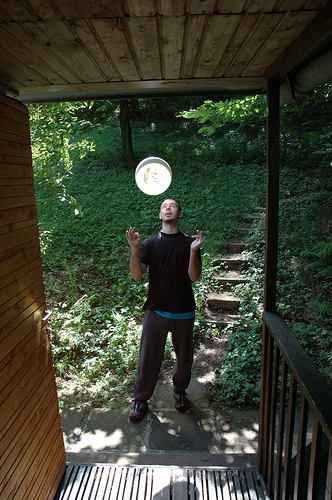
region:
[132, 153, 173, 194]
A white ball in the air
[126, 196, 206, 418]
A man outside catching the ball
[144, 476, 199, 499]
The shadow of the ball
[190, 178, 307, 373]
A pathway with steps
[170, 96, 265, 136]
A branch with leaves on it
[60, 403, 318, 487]
concrete slab patio outside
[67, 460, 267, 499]
The porch of the house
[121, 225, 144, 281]
The man's right arm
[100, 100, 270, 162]
A wooded area outside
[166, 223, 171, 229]
The man's Adams apple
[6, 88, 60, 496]
Light pine wood siding on house.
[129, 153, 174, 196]
White freebie in the air.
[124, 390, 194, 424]
Black, gray and red tennis shoes.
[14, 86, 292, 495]
Covered porch made of wood.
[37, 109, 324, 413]
Lots of green foliage for landscape.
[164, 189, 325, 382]
Wooden slates in dirt for natural stairs.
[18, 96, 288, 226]
Very little sun coming through the trees.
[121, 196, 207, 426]
Navy blue tee shirt with light blue shirt underneath.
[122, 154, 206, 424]
Man trying to catch freebie as it comes down.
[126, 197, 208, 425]
Comfortable sweatpants for kicking back.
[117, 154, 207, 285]
a man is standing under a pie pan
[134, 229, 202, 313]
the man is wearing a dark blue t-shirt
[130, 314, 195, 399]
the man's pants are warm ups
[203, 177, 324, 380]
a stepped pathway winds up a hill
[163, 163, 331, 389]
the pathway is surrounded by ivy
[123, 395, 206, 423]
the boy has tennis shoes on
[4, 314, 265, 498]
a wooden structure is in front of him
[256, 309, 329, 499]
a wooden fence is on the porch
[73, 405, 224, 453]
cement slabs are under the man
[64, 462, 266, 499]
the floor has wooden slats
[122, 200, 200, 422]
A man is wearing a black shirt.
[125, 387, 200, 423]
Black and red shoes.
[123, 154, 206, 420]
A man is throwing a round pan.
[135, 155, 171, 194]
A round metal pan.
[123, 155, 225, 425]
The man trying to catch a pan thrown to him.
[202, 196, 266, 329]
Concrete stairs going to the garden.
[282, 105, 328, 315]
Green trailing ivy bushes.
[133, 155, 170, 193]
A picture of yellow bird on the pan.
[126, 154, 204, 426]
A man looking intensely at the flying pan.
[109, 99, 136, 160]
A tree behind the man.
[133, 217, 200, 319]
the shirt is black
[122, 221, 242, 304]
the shirt is black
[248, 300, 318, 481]
the railings made of wood